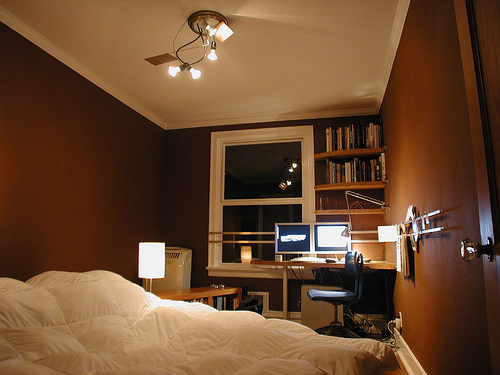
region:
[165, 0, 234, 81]
Lights hanging from ceiling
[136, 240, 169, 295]
Lamp next to bed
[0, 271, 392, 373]
White comforter on the bed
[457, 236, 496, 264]
Silver door knob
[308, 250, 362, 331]
Chair in front of the desk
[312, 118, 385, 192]
Books on a bookshelf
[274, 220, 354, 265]
Computer screens on the desk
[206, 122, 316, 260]
WIndow trimmed in white wood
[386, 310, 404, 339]
Cord plugged into wall outlet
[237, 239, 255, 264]
Reflection of lamp in window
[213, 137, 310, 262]
a window in a room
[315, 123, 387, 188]
books on bookshelves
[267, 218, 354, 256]
two side by side computer monitors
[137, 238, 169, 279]
a lamp that is turned on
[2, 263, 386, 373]
a white bed spread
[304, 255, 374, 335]
an office chair beside a desk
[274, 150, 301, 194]
light reflecting in a pane of glass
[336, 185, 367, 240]
a desk lamp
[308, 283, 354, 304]
the seat of a chair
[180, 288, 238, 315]
books on wooden shelves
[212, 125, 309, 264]
The window in the room.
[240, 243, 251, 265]
The candle on the windowsill.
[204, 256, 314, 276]
The windowsill of the window.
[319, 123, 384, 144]
The books on the top shelf.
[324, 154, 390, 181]
The books on the middle shelf.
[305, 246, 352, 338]
The chair in front of the desk.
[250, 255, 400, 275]
The desk the monitors are on.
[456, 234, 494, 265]
The door knob on the door.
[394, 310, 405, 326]
The electrical socket on the wall.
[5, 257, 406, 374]
The white quilt in the room.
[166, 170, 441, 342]
the view is in a bedoom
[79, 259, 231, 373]
the blsnket is white in color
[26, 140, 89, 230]
the walls are brown in color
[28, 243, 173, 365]
people are sleeping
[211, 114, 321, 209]
window panes are white in color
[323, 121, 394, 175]
books are arrnged on the shelf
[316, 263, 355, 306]
seat is black in color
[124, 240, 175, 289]
light is beside the table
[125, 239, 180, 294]
light is white in color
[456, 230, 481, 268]
door handle is silvery in color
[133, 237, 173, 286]
Crisp white table lamp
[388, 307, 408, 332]
Small electric wire cord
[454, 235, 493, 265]
Silver metal door handle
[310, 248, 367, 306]
Black colored swivel chair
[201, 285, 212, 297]
Smooth brown bedside cabinet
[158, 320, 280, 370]
Comfy white fluffy duvet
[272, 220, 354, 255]
Two white desktop computers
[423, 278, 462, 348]
Earth brown stone wall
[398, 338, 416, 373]
White colored wall base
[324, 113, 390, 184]
Neatly arranged book shelf